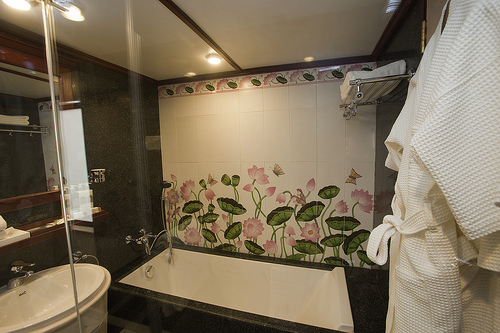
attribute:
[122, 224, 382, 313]
bathtub — here, white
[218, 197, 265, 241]
leaves — painted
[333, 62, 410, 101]
shelf — storing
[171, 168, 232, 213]
flowers — pink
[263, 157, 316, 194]
butterfly — painted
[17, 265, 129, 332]
sink — deep, oval, white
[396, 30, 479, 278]
robe — hanging, tied, straped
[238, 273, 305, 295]
mable — white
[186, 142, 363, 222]
tile — white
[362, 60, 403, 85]
towel — white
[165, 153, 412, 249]
design — pink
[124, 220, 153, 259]
faucet — silver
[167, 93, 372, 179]
wall — white, tile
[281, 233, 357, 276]
lily — green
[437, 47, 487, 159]
bathrobe — white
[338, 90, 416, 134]
rack — holding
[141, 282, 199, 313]
tile — grey